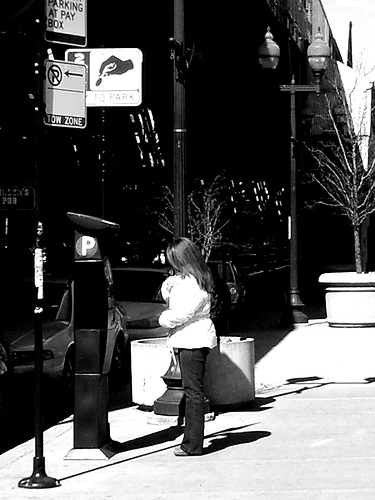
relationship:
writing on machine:
[73, 236, 98, 258] [63, 203, 118, 455]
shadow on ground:
[239, 389, 315, 418] [259, 358, 341, 483]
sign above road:
[41, 57, 89, 130] [16, 397, 121, 454]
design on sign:
[95, 57, 136, 81] [91, 34, 154, 117]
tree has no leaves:
[296, 90, 373, 271] [326, 78, 345, 90]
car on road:
[11, 280, 82, 386] [16, 397, 121, 454]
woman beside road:
[154, 229, 223, 445] [16, 397, 121, 454]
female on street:
[154, 229, 223, 445] [28, 382, 138, 468]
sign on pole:
[91, 34, 154, 117] [35, 132, 84, 220]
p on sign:
[69, 233, 106, 260] [91, 34, 154, 117]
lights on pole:
[254, 32, 337, 83] [275, 77, 318, 190]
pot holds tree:
[313, 256, 374, 330] [296, 90, 373, 271]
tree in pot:
[296, 90, 373, 271] [313, 256, 374, 330]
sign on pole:
[41, 57, 89, 130] [35, 132, 84, 220]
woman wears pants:
[154, 229, 223, 445] [177, 348, 219, 447]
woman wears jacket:
[154, 229, 223, 445] [158, 272, 227, 353]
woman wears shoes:
[154, 229, 223, 445] [172, 440, 199, 463]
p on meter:
[69, 233, 106, 260] [63, 203, 118, 455]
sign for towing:
[91, 34, 154, 117] [45, 110, 68, 128]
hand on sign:
[95, 57, 136, 81] [91, 34, 154, 117]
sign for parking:
[91, 34, 154, 117] [47, 0, 87, 16]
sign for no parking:
[41, 57, 96, 130] [45, 59, 68, 86]